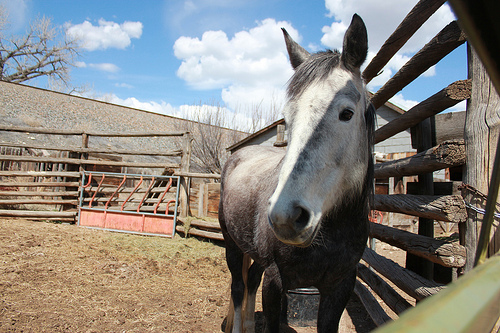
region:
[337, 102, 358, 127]
dark eye on a horse's face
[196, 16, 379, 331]
grey horse by a fence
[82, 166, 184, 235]
orange gate to an enclosure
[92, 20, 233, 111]
white puffy clouds in the sky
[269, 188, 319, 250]
white and grey nose on a horse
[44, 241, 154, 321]
hay covered ground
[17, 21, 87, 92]
bare branches on a tree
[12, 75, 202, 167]
shingled roof of a barn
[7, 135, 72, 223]
wooden slatted fence enclosure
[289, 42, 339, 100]
grey mane of a horse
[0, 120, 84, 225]
a brown wooden fence.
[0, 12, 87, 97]
a thin small leave less tree.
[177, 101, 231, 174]
the trees are small and thin.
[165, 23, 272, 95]
a blue sky is cloudy.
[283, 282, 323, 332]
a small black bucket.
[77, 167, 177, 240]
a big red piece of metal fence.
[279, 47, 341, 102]
a horse with a straight hair bang.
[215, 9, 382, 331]
the horse is brown and white.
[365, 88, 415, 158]
a light blue house.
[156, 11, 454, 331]
a horse is standing in the grass.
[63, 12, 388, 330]
a donkey in a pen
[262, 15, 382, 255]
the head of a donkey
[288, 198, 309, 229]
the nostril of a donkey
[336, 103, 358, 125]
the eye of a donkey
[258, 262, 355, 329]
the front legs of a donkey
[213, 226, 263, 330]
the rear legs of a donkey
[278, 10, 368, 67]
the ears of a donkey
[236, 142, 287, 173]
the back of a donkey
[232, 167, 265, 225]
the fur of a donkey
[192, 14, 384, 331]
The horse is black and white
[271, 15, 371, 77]
The horses ears are upright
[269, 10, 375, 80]
The horse's ears are pointing up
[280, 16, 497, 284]
The corral fence is wooden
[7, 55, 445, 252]
A ranch house is behind the corral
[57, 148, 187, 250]
A red metal gate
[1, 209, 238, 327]
Dried up grass is on the ground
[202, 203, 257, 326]
The horse's tail is hanging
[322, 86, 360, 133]
The horse's eye is open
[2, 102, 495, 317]
The horse is enclosed in the corral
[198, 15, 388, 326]
The horse is white and black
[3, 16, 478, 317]
The horse is in a corral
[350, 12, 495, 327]
The fence is wooden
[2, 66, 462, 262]
A ranch house in the background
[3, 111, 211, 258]
The wooden fence encloses the horse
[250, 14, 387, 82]
The horse's ears stand up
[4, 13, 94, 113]
Trees in the distance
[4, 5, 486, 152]
A partly cloudy sky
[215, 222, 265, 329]
The horse's tail hangs low